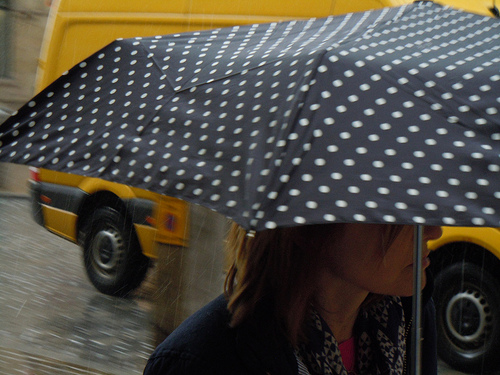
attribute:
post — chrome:
[408, 226, 425, 369]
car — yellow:
[166, 5, 233, 26]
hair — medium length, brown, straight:
[214, 217, 412, 348]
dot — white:
[372, 89, 386, 107]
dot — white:
[375, 117, 392, 131]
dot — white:
[400, 98, 420, 110]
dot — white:
[287, 186, 301, 196]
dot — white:
[385, 170, 404, 186]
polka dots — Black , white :
[95, 59, 460, 186]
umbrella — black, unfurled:
[10, 2, 499, 237]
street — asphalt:
[1, 196, 159, 373]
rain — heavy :
[93, 242, 190, 302]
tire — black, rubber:
[79, 200, 175, 309]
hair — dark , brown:
[221, 222, 403, 347]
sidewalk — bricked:
[4, 338, 152, 372]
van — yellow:
[36, 9, 490, 247]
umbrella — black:
[2, 1, 496, 373]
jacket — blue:
[142, 276, 437, 374]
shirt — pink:
[338, 333, 362, 373]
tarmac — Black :
[142, 195, 440, 373]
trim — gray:
[33, 175, 158, 226]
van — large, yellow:
[41, 10, 471, 307]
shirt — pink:
[139, 285, 441, 372]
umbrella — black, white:
[85, 31, 489, 265]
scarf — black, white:
[289, 277, 410, 373]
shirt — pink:
[334, 331, 356, 369]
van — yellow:
[28, 4, 480, 359]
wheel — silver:
[81, 194, 161, 303]